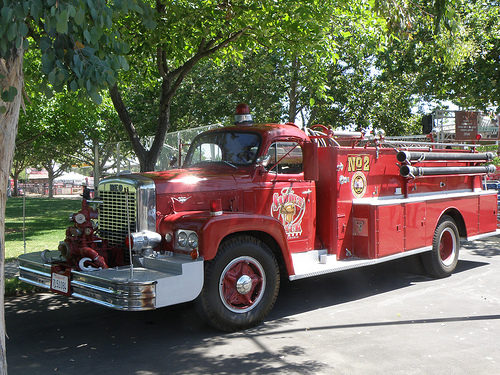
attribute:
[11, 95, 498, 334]
engine — red, parked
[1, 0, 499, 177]
branches — green, leafy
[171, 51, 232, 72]
branch — green, leafy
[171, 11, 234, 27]
branch — green, leafy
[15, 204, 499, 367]
street — paved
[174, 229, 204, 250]
headlight — off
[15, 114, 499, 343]
fire truck — red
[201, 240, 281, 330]
tire — black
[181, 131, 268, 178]
windshield — clear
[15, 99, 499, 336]
truck — big, red, silver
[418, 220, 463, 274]
tire — black